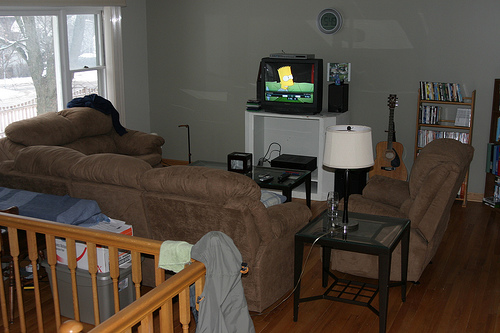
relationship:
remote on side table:
[259, 166, 270, 187] [204, 152, 315, 223]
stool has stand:
[292, 202, 412, 324] [311, 250, 371, 324]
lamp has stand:
[335, 125, 386, 247] [311, 250, 371, 324]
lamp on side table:
[335, 125, 386, 247] [292, 202, 412, 324]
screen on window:
[60, 17, 99, 78] [13, 22, 107, 115]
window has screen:
[13, 22, 107, 115] [60, 17, 99, 78]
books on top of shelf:
[417, 72, 468, 108] [397, 71, 480, 224]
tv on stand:
[205, 46, 342, 118] [233, 100, 344, 216]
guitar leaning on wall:
[372, 95, 406, 184] [133, 11, 498, 188]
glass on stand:
[301, 203, 410, 256] [292, 208, 411, 333]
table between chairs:
[183, 141, 327, 222] [50, 91, 427, 278]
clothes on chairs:
[78, 97, 127, 128] [0, 145, 313, 315]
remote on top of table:
[259, 166, 270, 187] [183, 141, 327, 222]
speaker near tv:
[317, 81, 358, 125] [205, 46, 342, 118]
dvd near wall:
[227, 147, 270, 192] [133, 11, 498, 188]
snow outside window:
[12, 77, 41, 109] [13, 22, 107, 115]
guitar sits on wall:
[372, 95, 406, 184] [133, 11, 498, 188]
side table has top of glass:
[292, 202, 412, 324] [301, 203, 410, 256]